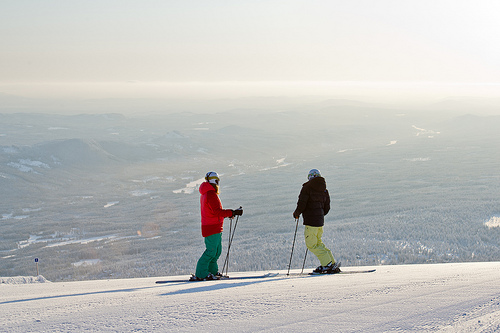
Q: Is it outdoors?
A: Yes, it is outdoors.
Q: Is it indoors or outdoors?
A: It is outdoors.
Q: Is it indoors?
A: No, it is outdoors.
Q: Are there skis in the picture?
A: Yes, there are skis.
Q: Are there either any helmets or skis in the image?
A: Yes, there are skis.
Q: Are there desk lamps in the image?
A: No, there are no desk lamps.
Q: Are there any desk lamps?
A: No, there are no desk lamps.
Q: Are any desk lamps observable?
A: No, there are no desk lamps.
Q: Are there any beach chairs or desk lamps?
A: No, there are no desk lamps or beach chairs.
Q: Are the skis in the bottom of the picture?
A: Yes, the skis are in the bottom of the image.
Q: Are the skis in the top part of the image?
A: No, the skis are in the bottom of the image.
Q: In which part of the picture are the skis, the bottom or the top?
A: The skis are in the bottom of the image.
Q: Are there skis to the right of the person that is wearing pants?
A: Yes, there are skis to the right of the person.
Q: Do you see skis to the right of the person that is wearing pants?
A: Yes, there are skis to the right of the person.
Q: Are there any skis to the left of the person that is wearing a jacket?
A: No, the skis are to the right of the person.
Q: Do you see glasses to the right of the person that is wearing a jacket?
A: No, there are skis to the right of the person.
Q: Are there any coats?
A: Yes, there is a coat.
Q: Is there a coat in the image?
A: Yes, there is a coat.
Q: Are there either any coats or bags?
A: Yes, there is a coat.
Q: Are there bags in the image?
A: No, there are no bags.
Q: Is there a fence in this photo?
A: No, there are no fences.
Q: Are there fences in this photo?
A: No, there are no fences.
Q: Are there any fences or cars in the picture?
A: No, there are no fences or cars.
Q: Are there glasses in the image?
A: No, there are no glasses.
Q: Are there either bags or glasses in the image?
A: No, there are no glasses or bags.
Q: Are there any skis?
A: Yes, there are skis.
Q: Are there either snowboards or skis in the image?
A: Yes, there are skis.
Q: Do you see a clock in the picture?
A: No, there are no clocks.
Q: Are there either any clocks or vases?
A: No, there are no clocks or vases.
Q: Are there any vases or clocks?
A: No, there are no clocks or vases.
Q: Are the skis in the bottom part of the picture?
A: Yes, the skis are in the bottom of the image.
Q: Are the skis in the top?
A: No, the skis are in the bottom of the image.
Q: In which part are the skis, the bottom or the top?
A: The skis are in the bottom of the image.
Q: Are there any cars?
A: No, there are no cars.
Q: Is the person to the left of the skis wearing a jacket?
A: Yes, the person is wearing a jacket.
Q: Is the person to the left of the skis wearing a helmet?
A: No, the person is wearing a jacket.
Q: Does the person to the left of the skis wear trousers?
A: Yes, the person wears trousers.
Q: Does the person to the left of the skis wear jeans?
A: No, the person wears trousers.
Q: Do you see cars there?
A: No, there are no cars.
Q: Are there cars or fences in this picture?
A: No, there are no cars or fences.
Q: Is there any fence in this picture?
A: No, there are no fences.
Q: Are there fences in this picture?
A: No, there are no fences.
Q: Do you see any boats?
A: No, there are no boats.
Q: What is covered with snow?
A: The mountains are covered with snow.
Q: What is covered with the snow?
A: The mountains are covered with snow.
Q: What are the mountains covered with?
A: The mountains are covered with snow.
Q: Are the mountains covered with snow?
A: Yes, the mountains are covered with snow.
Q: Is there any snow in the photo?
A: Yes, there is snow.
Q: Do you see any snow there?
A: Yes, there is snow.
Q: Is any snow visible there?
A: Yes, there is snow.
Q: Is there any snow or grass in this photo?
A: Yes, there is snow.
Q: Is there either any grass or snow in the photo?
A: Yes, there is snow.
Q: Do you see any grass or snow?
A: Yes, there is snow.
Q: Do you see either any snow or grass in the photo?
A: Yes, there is snow.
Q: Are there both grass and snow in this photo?
A: No, there is snow but no grass.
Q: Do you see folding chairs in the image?
A: No, there are no folding chairs.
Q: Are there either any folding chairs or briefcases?
A: No, there are no folding chairs or briefcases.